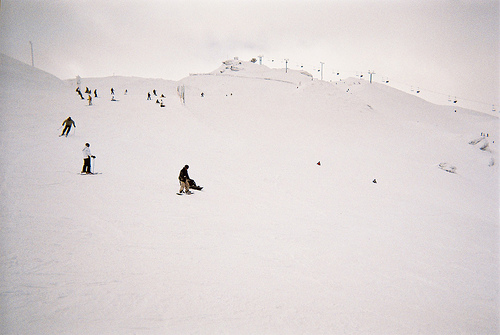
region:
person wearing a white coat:
[79, 145, 94, 160]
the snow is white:
[87, 210, 427, 333]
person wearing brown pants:
[179, 180, 192, 192]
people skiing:
[82, 87, 173, 110]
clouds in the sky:
[85, 15, 190, 69]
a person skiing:
[55, 117, 77, 140]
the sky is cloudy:
[377, 15, 476, 73]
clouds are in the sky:
[67, 20, 227, 59]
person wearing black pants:
[81, 158, 93, 172]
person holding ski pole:
[87, 154, 97, 176]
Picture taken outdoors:
[21, 21, 423, 328]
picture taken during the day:
[21, 19, 480, 334]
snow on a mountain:
[31, 73, 493, 329]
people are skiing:
[54, 85, 256, 203]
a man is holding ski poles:
[56, 109, 77, 136]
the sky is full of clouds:
[86, 12, 443, 62]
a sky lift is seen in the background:
[240, 40, 455, 133]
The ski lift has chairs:
[250, 50, 445, 130]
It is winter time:
[50, 110, 482, 311]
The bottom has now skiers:
[43, 231, 445, 317]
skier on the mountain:
[171, 162, 204, 214]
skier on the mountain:
[73, 139, 109, 181]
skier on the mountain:
[60, 115, 77, 142]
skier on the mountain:
[84, 95, 101, 110]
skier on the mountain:
[198, 87, 208, 109]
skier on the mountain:
[158, 103, 165, 110]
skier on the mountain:
[108, 94, 126, 109]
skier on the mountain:
[78, 91, 88, 101]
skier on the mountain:
[107, 85, 119, 95]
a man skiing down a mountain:
[172, 156, 207, 201]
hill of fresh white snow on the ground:
[5, 40, 495, 333]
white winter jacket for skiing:
[78, 143, 98, 160]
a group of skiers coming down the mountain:
[69, 78, 187, 116]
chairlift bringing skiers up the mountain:
[252, 47, 498, 116]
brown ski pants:
[175, 173, 192, 193]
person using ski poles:
[54, 112, 79, 136]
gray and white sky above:
[5, 3, 499, 97]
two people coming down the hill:
[310, 154, 383, 196]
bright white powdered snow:
[5, 45, 497, 330]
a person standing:
[171, 163, 195, 195]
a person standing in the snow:
[78, 141, 97, 176]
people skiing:
[71, 86, 118, 103]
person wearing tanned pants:
[177, 180, 193, 193]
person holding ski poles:
[90, 155, 100, 170]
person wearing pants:
[81, 158, 92, 171]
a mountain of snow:
[346, 72, 405, 119]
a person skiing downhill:
[60, 116, 81, 137]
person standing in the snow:
[84, 94, 94, 104]